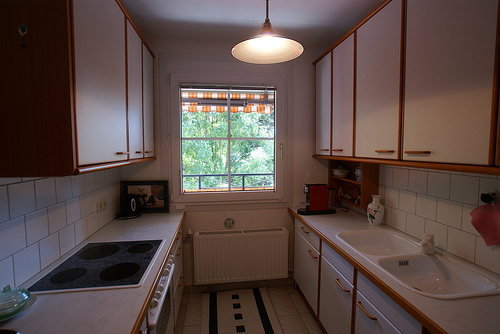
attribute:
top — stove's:
[25, 230, 168, 293]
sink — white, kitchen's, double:
[330, 221, 500, 298]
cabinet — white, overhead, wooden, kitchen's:
[400, 2, 498, 170]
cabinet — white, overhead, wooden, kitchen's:
[349, 3, 406, 158]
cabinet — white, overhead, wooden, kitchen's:
[327, 23, 359, 153]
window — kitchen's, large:
[180, 88, 279, 191]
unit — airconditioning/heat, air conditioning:
[195, 230, 288, 283]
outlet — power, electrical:
[96, 196, 110, 212]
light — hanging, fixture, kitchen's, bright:
[227, 0, 313, 71]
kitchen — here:
[9, 4, 497, 332]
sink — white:
[382, 246, 496, 296]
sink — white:
[331, 218, 424, 256]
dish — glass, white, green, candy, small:
[366, 193, 386, 224]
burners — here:
[50, 235, 157, 285]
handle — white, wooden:
[149, 259, 180, 328]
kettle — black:
[117, 189, 150, 220]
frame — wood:
[396, 4, 499, 175]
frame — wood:
[348, 4, 413, 166]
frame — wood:
[328, 23, 360, 165]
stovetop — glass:
[37, 229, 160, 292]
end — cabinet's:
[4, 4, 78, 177]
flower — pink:
[364, 200, 384, 215]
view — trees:
[184, 95, 274, 185]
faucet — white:
[412, 235, 447, 258]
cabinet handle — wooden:
[404, 149, 433, 155]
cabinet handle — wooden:
[372, 143, 397, 156]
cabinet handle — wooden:
[330, 141, 346, 150]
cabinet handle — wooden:
[315, 145, 329, 156]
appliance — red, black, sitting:
[296, 180, 343, 216]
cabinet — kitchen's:
[294, 221, 320, 299]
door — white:
[404, 2, 497, 157]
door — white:
[353, 4, 398, 155]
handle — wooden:
[404, 148, 433, 155]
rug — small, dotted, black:
[202, 281, 282, 329]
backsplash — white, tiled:
[5, 172, 141, 287]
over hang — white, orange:
[178, 88, 273, 114]